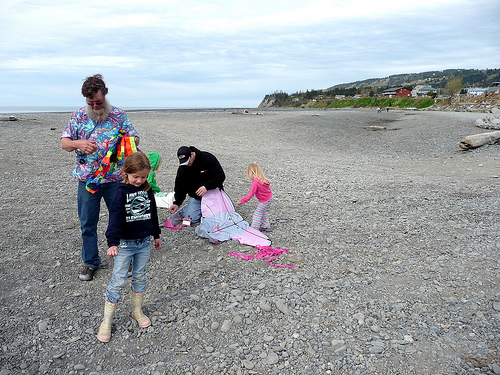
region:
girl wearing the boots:
[91, 149, 166, 356]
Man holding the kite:
[50, 47, 163, 339]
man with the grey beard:
[43, 50, 150, 315]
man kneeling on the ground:
[155, 128, 236, 237]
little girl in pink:
[227, 146, 322, 278]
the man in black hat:
[146, 130, 216, 190]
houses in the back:
[286, 70, 496, 126]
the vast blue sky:
[17, 15, 487, 105]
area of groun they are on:
[31, 161, 352, 349]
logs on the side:
[446, 94, 498, 182]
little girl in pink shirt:
[236, 163, 275, 232]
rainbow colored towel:
[114, 134, 136, 165]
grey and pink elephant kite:
[196, 186, 271, 251]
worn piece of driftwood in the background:
[456, 127, 499, 149]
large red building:
[384, 83, 411, 96]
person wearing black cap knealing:
[169, 143, 226, 224]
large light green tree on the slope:
[443, 76, 462, 96]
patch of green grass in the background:
[328, 96, 432, 110]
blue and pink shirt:
[61, 106, 137, 182]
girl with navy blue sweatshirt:
[94, 149, 164, 341]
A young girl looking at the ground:
[235, 161, 281, 245]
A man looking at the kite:
[166, 135, 224, 250]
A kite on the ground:
[191, 180, 277, 270]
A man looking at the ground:
[50, 75, 144, 282]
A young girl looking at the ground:
[87, 149, 170, 346]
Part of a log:
[461, 121, 499, 163]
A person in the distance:
[383, 103, 392, 116]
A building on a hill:
[461, 80, 498, 105]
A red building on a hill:
[381, 83, 414, 104]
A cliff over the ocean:
[258, 85, 291, 121]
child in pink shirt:
[230, 156, 288, 238]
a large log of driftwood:
[453, 115, 498, 155]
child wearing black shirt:
[77, 148, 168, 354]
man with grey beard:
[44, 65, 145, 282]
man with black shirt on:
[162, 143, 234, 232]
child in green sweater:
[142, 146, 168, 201]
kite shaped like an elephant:
[189, 175, 281, 252]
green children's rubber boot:
[91, 287, 125, 347]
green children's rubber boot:
[125, 276, 154, 333]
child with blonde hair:
[235, 161, 273, 231]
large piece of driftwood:
[456, 127, 498, 153]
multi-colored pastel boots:
[95, 289, 151, 344]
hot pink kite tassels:
[227, 244, 294, 266]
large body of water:
[125, 107, 300, 114]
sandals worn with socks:
[77, 264, 96, 282]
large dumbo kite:
[192, 187, 273, 252]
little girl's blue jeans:
[103, 233, 151, 307]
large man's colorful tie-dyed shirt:
[57, 102, 137, 184]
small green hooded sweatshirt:
[145, 149, 165, 196]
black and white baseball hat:
[175, 144, 192, 168]